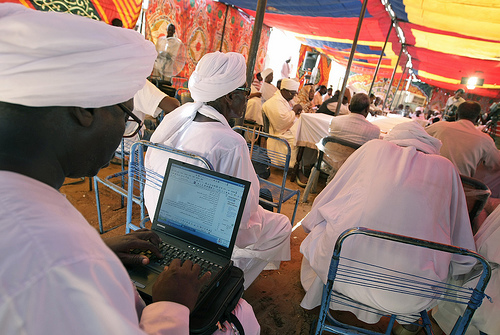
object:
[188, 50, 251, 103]
turban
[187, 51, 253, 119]
head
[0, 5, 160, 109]
turban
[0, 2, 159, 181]
head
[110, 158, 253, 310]
laptop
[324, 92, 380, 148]
person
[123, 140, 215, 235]
chair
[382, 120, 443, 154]
white turban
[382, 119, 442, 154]
head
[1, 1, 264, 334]
man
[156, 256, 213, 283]
fingers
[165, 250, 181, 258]
keyboard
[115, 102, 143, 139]
glasses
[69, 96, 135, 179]
face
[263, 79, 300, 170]
people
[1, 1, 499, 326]
room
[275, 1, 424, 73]
cloth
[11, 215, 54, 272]
white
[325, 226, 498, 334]
chairs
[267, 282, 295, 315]
dirt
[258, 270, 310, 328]
floor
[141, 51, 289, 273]
men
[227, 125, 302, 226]
blue chairs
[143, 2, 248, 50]
mural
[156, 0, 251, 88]
wall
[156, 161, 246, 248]
screen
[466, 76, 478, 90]
light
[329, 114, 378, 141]
white shirts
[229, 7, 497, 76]
stripes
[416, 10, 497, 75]
ceiling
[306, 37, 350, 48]
part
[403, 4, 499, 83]
surface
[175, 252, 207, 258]
part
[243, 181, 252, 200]
edge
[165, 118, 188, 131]
part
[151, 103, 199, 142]
cloth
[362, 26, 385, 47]
fabric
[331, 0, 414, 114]
poles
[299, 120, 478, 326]
man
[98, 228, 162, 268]
hands